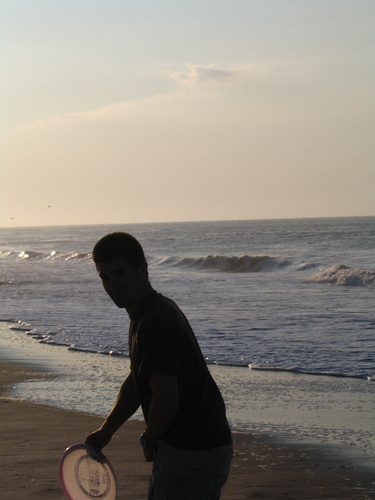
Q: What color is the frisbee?
A: Clear.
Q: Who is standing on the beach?
A: A guy.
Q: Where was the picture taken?
A: On a beach.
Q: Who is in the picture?
A: A man.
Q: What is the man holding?
A: Frisbee.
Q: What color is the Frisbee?
A: White.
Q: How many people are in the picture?
A: 1.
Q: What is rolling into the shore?
A: Waves.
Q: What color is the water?
A: Blue.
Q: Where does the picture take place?
A: Beach.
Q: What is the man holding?
A: A frisbee.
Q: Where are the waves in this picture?
A: Behind the man.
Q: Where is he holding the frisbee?
A: In his hand.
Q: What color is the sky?
A: Blue.